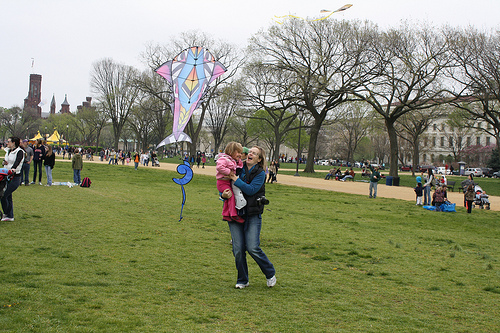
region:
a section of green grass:
[285, 205, 495, 330]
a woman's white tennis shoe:
[265, 271, 280, 286]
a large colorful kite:
[150, 45, 222, 140]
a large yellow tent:
[40, 125, 67, 145]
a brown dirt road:
[276, 166, 361, 191]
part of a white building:
[413, 100, 498, 161]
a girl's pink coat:
[208, 150, 245, 184]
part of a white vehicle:
[462, 166, 479, 175]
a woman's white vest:
[4, 146, 26, 171]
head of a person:
[242, 129, 276, 167]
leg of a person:
[219, 235, 247, 275]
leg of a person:
[233, 201, 290, 279]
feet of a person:
[227, 279, 255, 289]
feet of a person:
[265, 266, 290, 287]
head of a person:
[216, 141, 251, 163]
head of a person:
[0, 133, 30, 170]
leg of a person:
[0, 175, 34, 230]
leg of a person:
[45, 169, 65, 184]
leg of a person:
[27, 161, 48, 183]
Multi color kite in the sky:
[154, 30, 223, 147]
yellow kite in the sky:
[323, 0, 365, 18]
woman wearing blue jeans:
[218, 209, 275, 276]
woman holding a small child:
[196, 131, 250, 228]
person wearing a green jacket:
[68, 150, 87, 173]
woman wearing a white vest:
[3, 146, 28, 181]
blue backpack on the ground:
[419, 195, 459, 212]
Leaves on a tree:
[438, 94, 483, 134]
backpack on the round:
[77, 170, 97, 193]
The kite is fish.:
[153, 40, 224, 157]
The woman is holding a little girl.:
[213, 137, 282, 290]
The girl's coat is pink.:
[215, 149, 243, 179]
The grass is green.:
[0, 158, 498, 329]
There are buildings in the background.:
[24, 69, 104, 111]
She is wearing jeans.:
[225, 212, 277, 284]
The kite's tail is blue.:
[174, 158, 196, 221]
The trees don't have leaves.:
[82, 12, 499, 214]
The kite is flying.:
[315, 3, 361, 20]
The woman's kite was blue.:
[232, 161, 270, 220]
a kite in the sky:
[150, 40, 226, 222]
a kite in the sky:
[275, 0, 355, 28]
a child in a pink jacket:
[211, 138, 244, 223]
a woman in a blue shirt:
[218, 142, 276, 290]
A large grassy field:
[0, 161, 498, 328]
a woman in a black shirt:
[0, 135, 30, 223]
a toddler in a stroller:
[477, 188, 489, 205]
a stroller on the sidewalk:
[472, 182, 492, 210]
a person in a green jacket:
[69, 146, 85, 181]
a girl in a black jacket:
[39, 142, 57, 189]